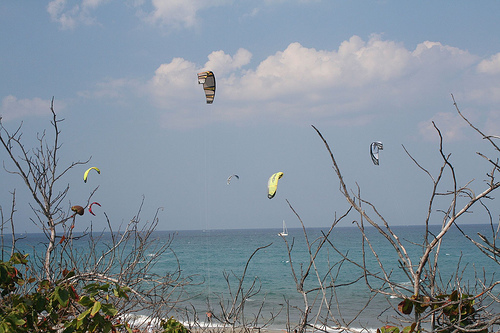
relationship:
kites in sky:
[60, 55, 313, 222] [1, 1, 499, 216]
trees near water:
[0, 111, 500, 323] [1, 229, 499, 325]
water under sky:
[1, 229, 499, 325] [1, 1, 499, 216]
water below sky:
[1, 229, 499, 325] [1, 1, 499, 216]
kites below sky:
[60, 55, 313, 222] [1, 1, 499, 216]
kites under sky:
[60, 55, 313, 222] [1, 1, 499, 216]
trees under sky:
[0, 111, 500, 323] [1, 1, 499, 216]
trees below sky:
[0, 111, 500, 323] [1, 1, 499, 216]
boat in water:
[274, 215, 295, 245] [1, 229, 499, 325]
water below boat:
[1, 229, 499, 325] [274, 215, 295, 245]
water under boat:
[1, 229, 499, 325] [274, 215, 295, 245]